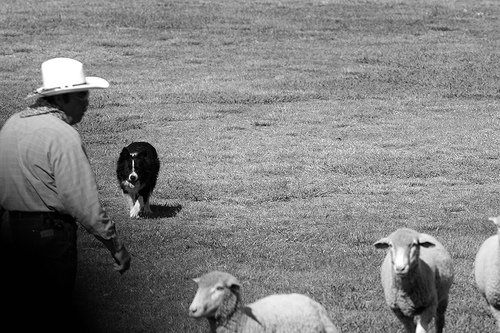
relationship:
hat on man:
[22, 50, 136, 100] [4, 56, 138, 328]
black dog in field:
[139, 144, 145, 161] [4, 0, 497, 321]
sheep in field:
[371, 227, 453, 331] [4, 0, 497, 321]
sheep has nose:
[187, 263, 340, 331] [192, 309, 199, 315]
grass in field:
[74, 5, 496, 222] [88, 23, 465, 214]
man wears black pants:
[15, 53, 129, 310] [2, 219, 95, 323]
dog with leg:
[111, 135, 164, 220] [127, 192, 138, 215]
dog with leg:
[111, 135, 164, 220] [130, 196, 142, 222]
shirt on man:
[1, 101, 123, 245] [4, 56, 138, 328]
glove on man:
[102, 246, 144, 277] [0, 20, 118, 305]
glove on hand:
[102, 246, 144, 277] [94, 204, 185, 289]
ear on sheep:
[374, 234, 394, 256] [359, 220, 465, 311]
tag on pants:
[35, 225, 59, 239] [0, 204, 89, 321]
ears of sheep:
[362, 234, 439, 250] [373, 209, 460, 331]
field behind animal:
[4, 0, 497, 321] [118, 138, 160, 218]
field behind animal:
[4, 0, 497, 321] [185, 268, 338, 331]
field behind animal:
[4, 0, 497, 321] [371, 226, 456, 331]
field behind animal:
[4, 0, 497, 321] [468, 213, 499, 323]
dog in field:
[111, 135, 164, 220] [4, 0, 497, 321]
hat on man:
[22, 50, 136, 100] [0, 30, 178, 329]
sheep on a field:
[461, 202, 498, 317] [4, 0, 497, 321]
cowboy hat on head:
[22, 55, 115, 103] [24, 56, 106, 124]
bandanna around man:
[20, 106, 62, 118] [1, 52, 127, 331]